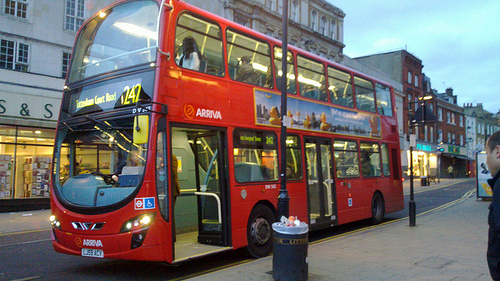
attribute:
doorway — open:
[164, 126, 226, 249]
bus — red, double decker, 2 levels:
[67, 8, 415, 259]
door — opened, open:
[173, 131, 227, 235]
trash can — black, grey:
[274, 203, 313, 280]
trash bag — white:
[277, 215, 307, 238]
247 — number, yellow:
[113, 84, 143, 112]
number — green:
[122, 84, 147, 107]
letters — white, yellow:
[196, 106, 231, 124]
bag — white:
[281, 222, 305, 237]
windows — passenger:
[167, 23, 373, 109]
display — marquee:
[62, 79, 155, 104]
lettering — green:
[70, 96, 118, 107]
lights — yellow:
[68, 80, 148, 108]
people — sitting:
[182, 35, 288, 84]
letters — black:
[1, 98, 56, 113]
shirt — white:
[182, 54, 212, 77]